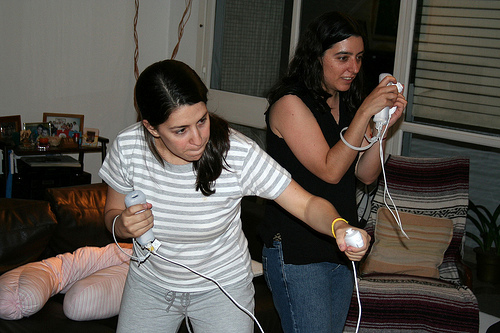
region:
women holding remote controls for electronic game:
[77, 16, 439, 312]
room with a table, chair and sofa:
[11, 5, 471, 310]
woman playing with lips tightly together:
[115, 42, 232, 193]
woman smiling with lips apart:
[282, 12, 432, 164]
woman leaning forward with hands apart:
[85, 45, 372, 325]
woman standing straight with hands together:
[265, 15, 425, 187]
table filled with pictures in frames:
[2, 56, 112, 186]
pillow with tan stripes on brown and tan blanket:
[365, 147, 480, 327]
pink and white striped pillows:
[0, 230, 130, 320]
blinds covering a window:
[406, 2, 494, 139]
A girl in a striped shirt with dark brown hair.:
[104, 58, 372, 331]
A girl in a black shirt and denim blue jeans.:
[261, 14, 406, 331]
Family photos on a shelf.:
[0, 111, 100, 151]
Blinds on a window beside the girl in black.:
[402, 2, 499, 135]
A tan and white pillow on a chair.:
[360, 204, 452, 286]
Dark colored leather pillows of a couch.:
[0, 184, 107, 253]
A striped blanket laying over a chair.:
[340, 151, 480, 331]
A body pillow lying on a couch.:
[1, 242, 139, 324]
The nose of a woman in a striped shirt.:
[188, 125, 201, 149]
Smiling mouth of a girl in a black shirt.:
[337, 72, 353, 84]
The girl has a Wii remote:
[310, 186, 410, 300]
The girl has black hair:
[104, 48, 245, 193]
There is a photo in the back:
[31, 101, 116, 189]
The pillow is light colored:
[365, 198, 477, 313]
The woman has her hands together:
[353, 53, 429, 209]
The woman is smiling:
[320, 42, 377, 136]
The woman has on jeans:
[257, 240, 374, 327]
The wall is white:
[29, 28, 130, 108]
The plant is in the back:
[458, 179, 498, 297]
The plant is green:
[464, 196, 497, 247]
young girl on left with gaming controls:
[90, 48, 375, 330]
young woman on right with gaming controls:
[262, 13, 383, 323]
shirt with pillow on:
[370, 199, 462, 302]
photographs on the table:
[2, 107, 99, 164]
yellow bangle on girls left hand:
[325, 212, 347, 232]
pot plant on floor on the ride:
[452, 189, 497, 297]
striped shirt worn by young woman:
[97, 108, 265, 310]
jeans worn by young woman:
[257, 216, 363, 331]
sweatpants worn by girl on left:
[110, 261, 264, 331]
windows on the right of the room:
[200, 1, 499, 137]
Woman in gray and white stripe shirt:
[99, 54, 285, 325]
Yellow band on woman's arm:
[323, 209, 350, 239]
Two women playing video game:
[103, 22, 418, 330]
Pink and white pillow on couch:
[0, 264, 118, 317]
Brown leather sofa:
[10, 176, 106, 247]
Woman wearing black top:
[259, 23, 401, 274]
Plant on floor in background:
[461, 195, 499, 286]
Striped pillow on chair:
[362, 200, 456, 285]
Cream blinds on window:
[403, 7, 499, 130]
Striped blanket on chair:
[342, 153, 489, 332]